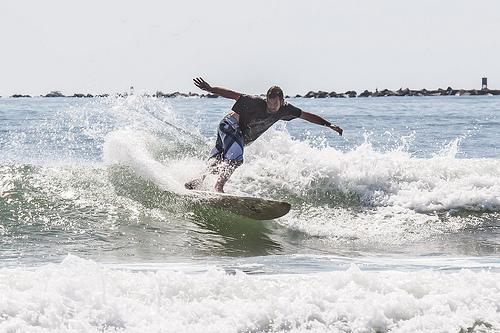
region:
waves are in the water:
[138, 30, 363, 258]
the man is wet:
[179, 45, 344, 255]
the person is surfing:
[186, 20, 327, 278]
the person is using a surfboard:
[176, 54, 334, 266]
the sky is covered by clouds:
[290, 41, 349, 76]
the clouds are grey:
[331, 32, 371, 80]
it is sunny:
[13, 7, 428, 331]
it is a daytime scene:
[21, 25, 411, 326]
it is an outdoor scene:
[13, 20, 434, 310]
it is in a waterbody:
[12, 39, 499, 327]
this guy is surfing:
[135, 81, 443, 238]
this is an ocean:
[55, 201, 303, 330]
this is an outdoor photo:
[55, 101, 383, 331]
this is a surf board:
[178, 159, 334, 246]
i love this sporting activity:
[97, 63, 487, 210]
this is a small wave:
[111, 147, 198, 310]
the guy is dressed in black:
[206, 62, 297, 169]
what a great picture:
[44, 84, 429, 327]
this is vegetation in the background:
[360, 61, 455, 100]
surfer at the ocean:
[14, 6, 486, 328]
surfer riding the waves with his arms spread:
[155, 54, 369, 225]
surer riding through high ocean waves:
[140, 53, 368, 240]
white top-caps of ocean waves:
[19, 68, 497, 309]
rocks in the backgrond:
[21, 39, 498, 199]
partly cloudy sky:
[10, 9, 497, 208]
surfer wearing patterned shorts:
[189, 74, 335, 239]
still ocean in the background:
[12, 96, 497, 141]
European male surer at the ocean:
[163, 81, 369, 264]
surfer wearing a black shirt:
[155, 79, 385, 239]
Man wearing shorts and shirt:
[130, 68, 343, 218]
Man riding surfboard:
[84, 52, 384, 242]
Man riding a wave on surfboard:
[133, 50, 350, 232]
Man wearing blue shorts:
[138, 38, 367, 255]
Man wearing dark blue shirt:
[154, 50, 350, 227]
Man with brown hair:
[118, 17, 368, 241]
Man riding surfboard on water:
[123, 63, 355, 215]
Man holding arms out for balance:
[125, 37, 366, 247]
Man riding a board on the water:
[132, 46, 359, 258]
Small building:
[475, 68, 494, 103]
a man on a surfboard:
[188, 73, 329, 224]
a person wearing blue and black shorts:
[210, 116, 252, 168]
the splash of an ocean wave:
[320, 132, 409, 157]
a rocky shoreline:
[327, 86, 422, 100]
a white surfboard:
[178, 189, 293, 223]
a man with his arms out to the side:
[181, 64, 363, 157]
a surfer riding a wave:
[136, 75, 349, 237]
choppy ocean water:
[382, 100, 456, 128]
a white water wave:
[78, 262, 344, 323]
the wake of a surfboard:
[162, 154, 202, 190]